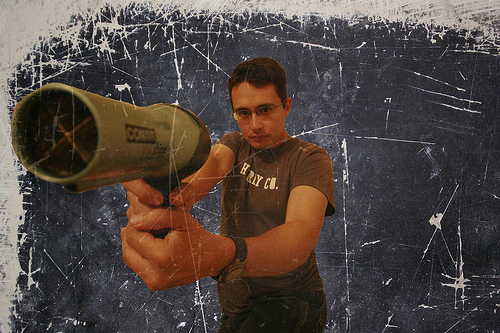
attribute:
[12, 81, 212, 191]
dryer — green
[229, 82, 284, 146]
face — serious looking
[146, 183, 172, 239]
handle — black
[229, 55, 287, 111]
brown hair — parted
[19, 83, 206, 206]
dryer — brown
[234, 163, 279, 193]
lettering — white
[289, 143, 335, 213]
sleeve — short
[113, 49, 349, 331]
man — watching, young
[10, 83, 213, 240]
blowdryer — pointed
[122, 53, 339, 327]
man — young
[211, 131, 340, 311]
t-shirt — brown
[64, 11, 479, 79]
wall — scratched up